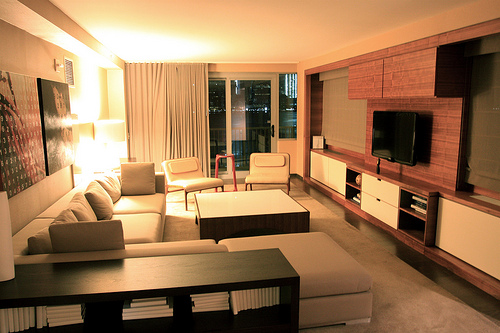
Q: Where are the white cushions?
A: On the couch.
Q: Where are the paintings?
A: On the wall.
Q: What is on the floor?
A: The rug.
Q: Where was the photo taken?
A: In a room.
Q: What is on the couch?
A: Pillows.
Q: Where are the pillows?
A: On the couch.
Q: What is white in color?
A: The couch.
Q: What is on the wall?
A: The television.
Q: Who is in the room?
A: No people.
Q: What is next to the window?
A: Curtains.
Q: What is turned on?
A: The light.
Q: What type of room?
A: A living room.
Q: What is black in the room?
A: A long dresser.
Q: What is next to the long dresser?
A: A sofa.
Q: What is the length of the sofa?
A: Long.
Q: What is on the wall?
A: A tv.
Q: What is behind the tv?
A: Wood.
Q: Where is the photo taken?
A: Living room.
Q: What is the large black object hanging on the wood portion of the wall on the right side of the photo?
A: TV.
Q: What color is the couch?
A: White.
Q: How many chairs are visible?
A: Two.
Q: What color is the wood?
A: Brown.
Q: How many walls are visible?
A: Three.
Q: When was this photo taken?
A: Night.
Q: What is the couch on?
A: Carpet.